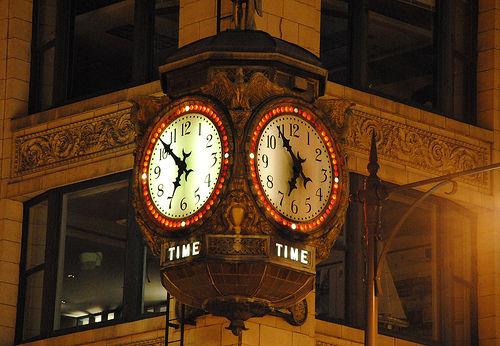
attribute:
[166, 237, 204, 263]
sign — TIME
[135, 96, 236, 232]
clock — left-side, large, hanging, lit up, white, round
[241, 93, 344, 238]
clock — right-side, large, hanging, lit up, white, round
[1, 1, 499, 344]
building — brown, decorative, behind, stone, fancy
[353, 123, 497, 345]
light pole — right-side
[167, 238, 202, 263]
word — illuminated, lit up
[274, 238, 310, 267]
word — illuminated, lit up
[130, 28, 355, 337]
structure — brown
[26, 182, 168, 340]
office — empty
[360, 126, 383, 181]
point — ornate